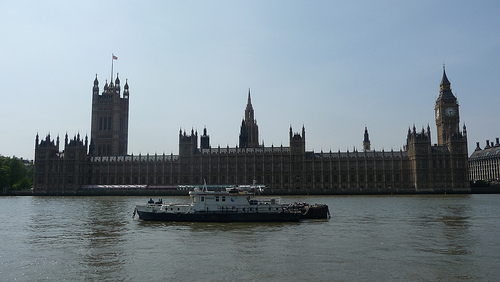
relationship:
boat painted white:
[132, 178, 333, 222] [175, 193, 280, 244]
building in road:
[33, 51, 500, 192] [18, 190, 473, 198]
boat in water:
[131, 168, 368, 236] [2, 195, 499, 280]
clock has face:
[445, 105, 457, 118] [444, 108, 458, 115]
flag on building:
[113, 55, 119, 60] [33, 51, 472, 191]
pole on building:
[99, 51, 118, 95] [19, 80, 486, 199]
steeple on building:
[239, 92, 264, 147] [93, 132, 470, 191]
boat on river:
[132, 178, 333, 222] [1, 198, 499, 279]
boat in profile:
[132, 178, 333, 222] [81, 120, 382, 258]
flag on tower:
[109, 53, 119, 60] [83, 45, 138, 157]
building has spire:
[33, 51, 472, 191] [246, 87, 251, 103]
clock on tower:
[445, 105, 457, 122] [433, 57, 475, 181]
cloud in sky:
[174, 47, 218, 92] [1, 0, 498, 160]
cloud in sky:
[2, 127, 26, 149] [1, 0, 498, 160]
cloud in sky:
[226, 17, 302, 77] [1, 3, 497, 143]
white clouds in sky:
[144, 34, 229, 97] [1, 3, 497, 143]